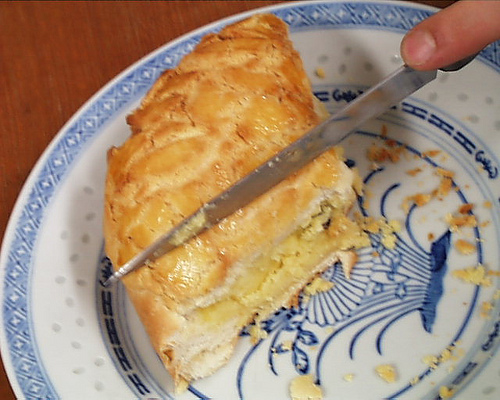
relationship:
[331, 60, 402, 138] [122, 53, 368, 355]
knife cutting pie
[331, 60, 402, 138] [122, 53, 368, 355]
knife on pie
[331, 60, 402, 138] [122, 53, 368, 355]
knife in pie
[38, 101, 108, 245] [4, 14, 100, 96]
plate on table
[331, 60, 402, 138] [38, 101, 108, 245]
knife on plate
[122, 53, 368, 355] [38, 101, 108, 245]
pie near plate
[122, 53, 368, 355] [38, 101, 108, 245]
pie on plate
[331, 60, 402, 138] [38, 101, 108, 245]
knife near plate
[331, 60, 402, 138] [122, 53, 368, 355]
knife near pie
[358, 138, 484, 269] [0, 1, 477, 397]
crumbs on plate